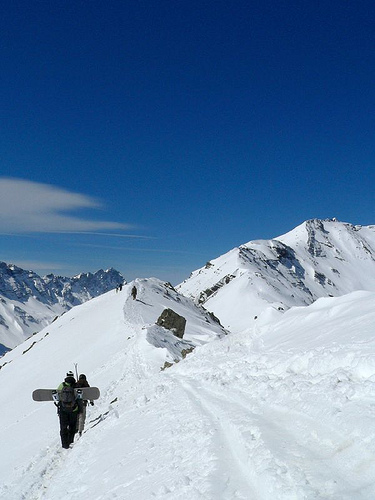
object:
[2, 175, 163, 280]
cloud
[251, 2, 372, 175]
sky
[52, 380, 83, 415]
back pack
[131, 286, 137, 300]
person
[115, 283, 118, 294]
person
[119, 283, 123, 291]
person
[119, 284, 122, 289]
clothing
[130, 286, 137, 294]
coat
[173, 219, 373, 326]
mountain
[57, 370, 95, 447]
two men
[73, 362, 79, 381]
stick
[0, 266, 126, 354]
mountain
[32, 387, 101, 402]
snow board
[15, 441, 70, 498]
foot prints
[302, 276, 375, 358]
snow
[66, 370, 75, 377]
hat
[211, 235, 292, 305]
snow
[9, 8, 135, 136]
sky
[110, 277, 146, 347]
ice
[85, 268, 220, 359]
mountain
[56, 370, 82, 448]
man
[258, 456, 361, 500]
snow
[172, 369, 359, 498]
tracks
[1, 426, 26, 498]
snow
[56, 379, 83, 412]
jacket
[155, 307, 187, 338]
boulder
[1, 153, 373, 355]
background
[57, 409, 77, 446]
pants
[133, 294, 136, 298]
pants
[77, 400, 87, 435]
pants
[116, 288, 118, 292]
pants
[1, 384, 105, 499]
ice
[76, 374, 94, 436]
men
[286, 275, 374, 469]
ice